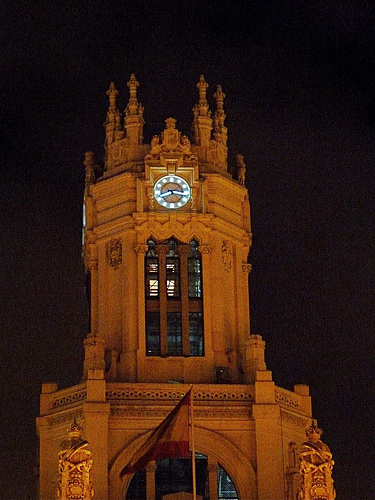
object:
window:
[142, 234, 163, 354]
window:
[164, 229, 185, 349]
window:
[185, 230, 204, 359]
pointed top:
[142, 229, 158, 247]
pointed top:
[164, 232, 182, 243]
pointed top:
[186, 231, 205, 249]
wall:
[89, 100, 290, 459]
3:
[182, 189, 188, 195]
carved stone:
[290, 424, 340, 497]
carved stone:
[57, 420, 93, 497]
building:
[30, 68, 339, 499]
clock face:
[152, 172, 193, 210]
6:
[171, 198, 180, 209]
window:
[220, 464, 240, 495]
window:
[155, 452, 209, 493]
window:
[126, 465, 146, 495]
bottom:
[31, 329, 340, 489]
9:
[155, 183, 162, 194]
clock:
[145, 166, 193, 210]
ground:
[310, 125, 350, 153]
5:
[175, 200, 183, 208]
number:
[179, 196, 187, 206]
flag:
[119, 383, 206, 497]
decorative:
[106, 230, 124, 278]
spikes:
[84, 60, 261, 196]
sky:
[0, 0, 375, 500]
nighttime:
[255, 99, 342, 304]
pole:
[187, 391, 202, 498]